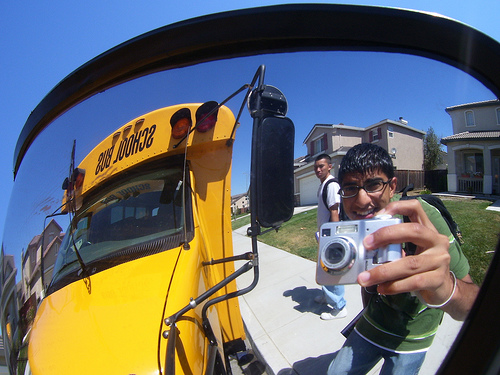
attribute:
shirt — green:
[344, 197, 472, 361]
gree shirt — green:
[346, 201, 471, 353]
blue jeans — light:
[323, 328, 426, 373]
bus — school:
[26, 99, 248, 373]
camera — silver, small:
[315, 216, 407, 293]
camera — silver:
[319, 214, 415, 285]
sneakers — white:
[276, 270, 357, 320]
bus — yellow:
[1, 92, 296, 367]